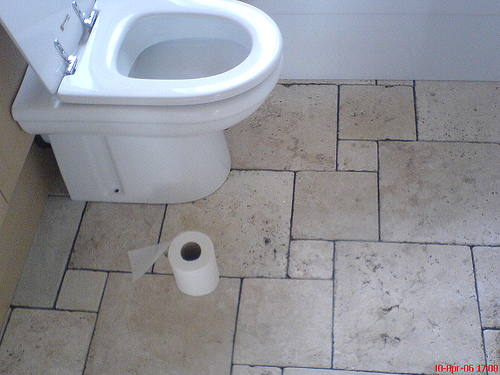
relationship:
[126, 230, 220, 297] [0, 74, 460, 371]
roll on bottom of floor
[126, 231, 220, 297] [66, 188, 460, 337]
tissue on floor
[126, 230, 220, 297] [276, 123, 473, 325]
roll on floor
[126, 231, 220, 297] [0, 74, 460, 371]
tissue on floor